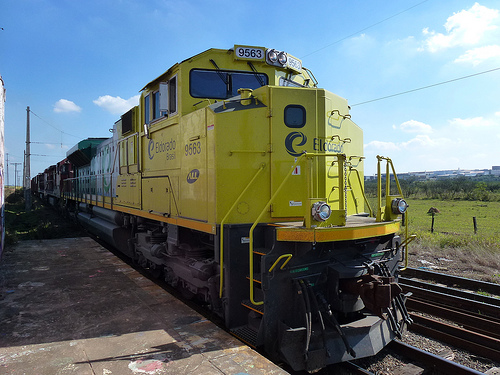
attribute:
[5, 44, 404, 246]
train — yellow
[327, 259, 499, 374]
tracks — railroad, metal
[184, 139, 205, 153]
number — 9563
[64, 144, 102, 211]
train cars — green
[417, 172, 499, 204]
tree — green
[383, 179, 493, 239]
grass — green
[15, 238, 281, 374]
platform — brown, concrete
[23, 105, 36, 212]
tower — elctrical, telephone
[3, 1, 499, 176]
sky — blue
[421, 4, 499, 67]
clouds — white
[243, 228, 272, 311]
stairs — yellow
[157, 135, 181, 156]
word — eldorado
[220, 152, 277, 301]
rails — yellow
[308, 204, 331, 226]
headlight — blue, round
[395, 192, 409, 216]
headlight — blue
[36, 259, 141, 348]
paint — white, red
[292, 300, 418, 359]
cattle guard — black